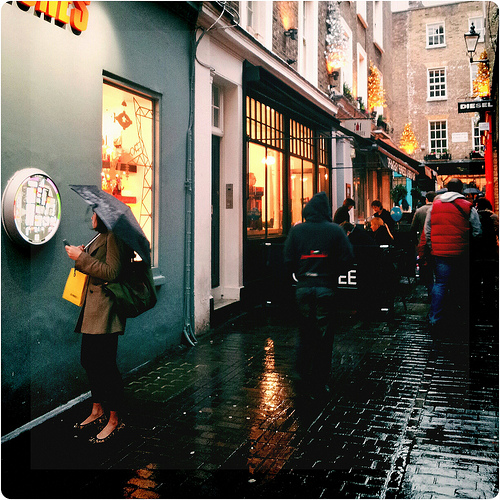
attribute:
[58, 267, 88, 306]
bag — yellow 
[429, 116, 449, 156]
window — glass 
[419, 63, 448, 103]
window — glass 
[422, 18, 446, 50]
window — glass 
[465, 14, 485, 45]
window — glass 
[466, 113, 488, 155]
window — glass 